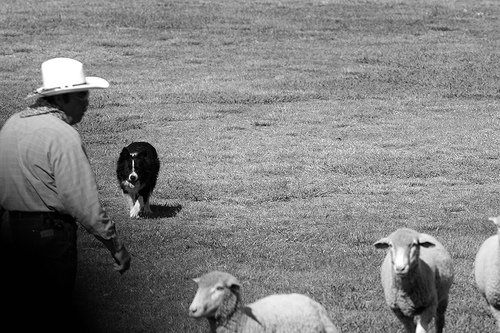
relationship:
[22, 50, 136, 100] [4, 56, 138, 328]
hat on man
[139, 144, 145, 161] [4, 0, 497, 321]
black dog in field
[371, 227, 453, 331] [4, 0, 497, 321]
sheep in field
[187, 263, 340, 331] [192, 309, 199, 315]
sheep has nose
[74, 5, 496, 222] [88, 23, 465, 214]
grass in field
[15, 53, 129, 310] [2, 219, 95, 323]
man wears black pants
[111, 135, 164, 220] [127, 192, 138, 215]
dog with leg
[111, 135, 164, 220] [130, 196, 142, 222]
dog with leg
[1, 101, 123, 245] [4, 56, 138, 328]
shirt on man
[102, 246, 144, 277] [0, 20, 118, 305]
glove on man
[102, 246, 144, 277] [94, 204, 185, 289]
glove on hand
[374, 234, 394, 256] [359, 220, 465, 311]
ear on sheep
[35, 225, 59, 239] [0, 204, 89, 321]
tag on pants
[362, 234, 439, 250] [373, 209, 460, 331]
ears of sheep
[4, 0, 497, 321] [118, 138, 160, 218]
field behind animal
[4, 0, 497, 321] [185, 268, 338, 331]
field behind animal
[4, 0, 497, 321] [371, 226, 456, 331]
field behind animal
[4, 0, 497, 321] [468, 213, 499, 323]
field behind animal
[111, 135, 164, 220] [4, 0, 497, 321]
dog in field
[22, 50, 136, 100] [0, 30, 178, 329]
hat on man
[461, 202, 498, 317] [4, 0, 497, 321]
sheep on a field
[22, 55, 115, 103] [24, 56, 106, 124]
cowboy hat on head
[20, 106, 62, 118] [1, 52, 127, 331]
bandanna around man